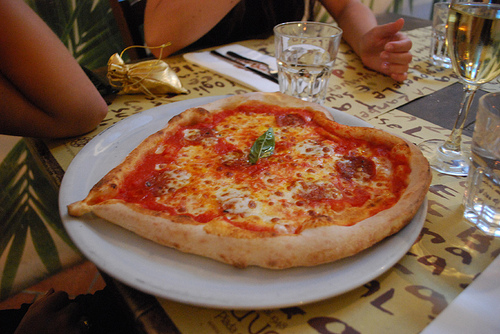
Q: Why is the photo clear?
A: Its during the day.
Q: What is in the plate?
A: Pizza.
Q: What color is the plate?
A: White.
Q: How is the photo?
A: Clear.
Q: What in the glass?
A: Wine.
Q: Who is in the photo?
A: People.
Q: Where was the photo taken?
A: In a restaurant.